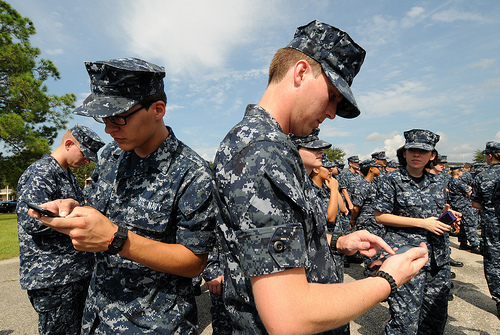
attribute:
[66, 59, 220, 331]
man — military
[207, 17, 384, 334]
man — military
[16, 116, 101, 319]
man — military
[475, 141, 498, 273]
man — military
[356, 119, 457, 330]
woman — military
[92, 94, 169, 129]
eye glasses — Black, framed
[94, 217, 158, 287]
watch — black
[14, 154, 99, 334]
uniform — military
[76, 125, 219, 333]
uniform — military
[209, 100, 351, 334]
uniform — military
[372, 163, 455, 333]
uniform — military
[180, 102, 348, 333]
uniforms — navy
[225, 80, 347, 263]
uniform — military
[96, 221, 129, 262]
watch — black strap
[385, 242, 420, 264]
phone — black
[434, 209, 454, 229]
phone — black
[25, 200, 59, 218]
phone — black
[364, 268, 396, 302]
bracelet — black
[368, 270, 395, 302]
bracelet — black, para cord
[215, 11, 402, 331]
soldiers — ground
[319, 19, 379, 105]
uniform hat — blue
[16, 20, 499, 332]
men — US Navy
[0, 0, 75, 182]
leaves — green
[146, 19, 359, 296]
uniform — military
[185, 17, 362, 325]
man — military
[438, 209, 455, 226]
phone — black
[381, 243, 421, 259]
phone — black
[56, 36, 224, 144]
cap — grey, camo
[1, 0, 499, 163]
sky — blue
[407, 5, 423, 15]
cloud — white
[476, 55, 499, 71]
cloud — white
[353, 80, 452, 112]
cloud — white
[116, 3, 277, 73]
cloud — white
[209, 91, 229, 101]
cloud — white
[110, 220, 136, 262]
wristwatch — black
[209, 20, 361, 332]
uniform — military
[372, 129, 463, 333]
uniform — military